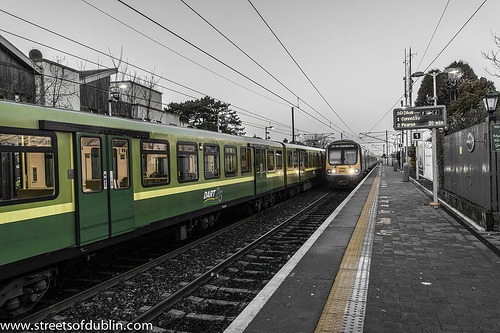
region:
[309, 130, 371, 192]
the train's headlights are on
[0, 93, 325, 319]
the train is green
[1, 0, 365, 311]
power lines above the trains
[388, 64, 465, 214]
a sign on the street light post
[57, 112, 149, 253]
the train has a double door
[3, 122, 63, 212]
a window beside the door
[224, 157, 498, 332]
a walkway next to the train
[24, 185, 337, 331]
the train tracks are metal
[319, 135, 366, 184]
the train has a windshield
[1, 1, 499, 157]
the sky is gray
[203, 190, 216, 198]
The word Dart on the side of a train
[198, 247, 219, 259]
gravel between railroad tracks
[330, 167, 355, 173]
the front headlights on a train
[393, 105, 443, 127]
white text on a black sign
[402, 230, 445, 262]
gray tiles on the platform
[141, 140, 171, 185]
a passenger window on the train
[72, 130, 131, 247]
double doors on the side of a green train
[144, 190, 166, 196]
a yellow stripe along the right side of the train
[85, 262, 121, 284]
metal train tracks beneath a train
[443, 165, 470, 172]
light reflecting off the side of a train car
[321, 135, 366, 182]
this is a train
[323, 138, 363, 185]
the train is in motion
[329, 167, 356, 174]
the light is on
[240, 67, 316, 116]
the electric lines are above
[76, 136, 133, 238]
the door is closed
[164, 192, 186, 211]
the train is green in color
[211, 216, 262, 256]
these are train rails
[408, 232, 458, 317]
this is a pavement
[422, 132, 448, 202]
this is a pole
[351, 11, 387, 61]
the sky is grey in color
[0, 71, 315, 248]
train is green and yellow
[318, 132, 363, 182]
front of train is yellow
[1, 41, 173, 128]
trees have no leaves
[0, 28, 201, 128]
buildings behind the train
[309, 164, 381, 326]
yellow line on platform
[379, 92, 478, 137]
sign on the platform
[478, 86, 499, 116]
streetlight is turned off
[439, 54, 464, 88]
street light is turned on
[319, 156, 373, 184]
train lights turned on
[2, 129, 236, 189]
lights on train are on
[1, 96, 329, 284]
a long dark green and light green train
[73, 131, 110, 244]
the dark green and black train door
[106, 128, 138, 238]
the dark green and black train door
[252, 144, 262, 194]
the dark green and black train door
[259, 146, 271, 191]
the dark green and black train door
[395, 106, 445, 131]
the black and yellow train sign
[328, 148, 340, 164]
the window of a train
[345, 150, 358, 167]
the window of a train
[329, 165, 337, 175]
the front headlight turned on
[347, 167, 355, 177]
the front headlight turned on